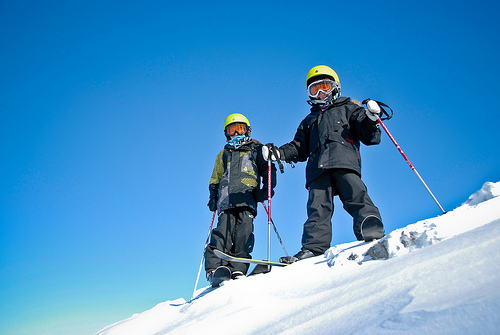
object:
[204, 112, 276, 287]
people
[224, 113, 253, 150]
helmet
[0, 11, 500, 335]
sky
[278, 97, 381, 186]
jacket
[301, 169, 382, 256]
pants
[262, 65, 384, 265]
people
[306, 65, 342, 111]
helmet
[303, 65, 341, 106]
head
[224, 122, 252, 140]
goggles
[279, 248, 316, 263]
boot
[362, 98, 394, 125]
strap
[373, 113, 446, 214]
design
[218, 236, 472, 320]
snow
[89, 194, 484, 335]
ground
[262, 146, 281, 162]
glove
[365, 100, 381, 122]
glove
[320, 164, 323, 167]
button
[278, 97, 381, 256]
snowsuit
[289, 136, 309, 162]
elbow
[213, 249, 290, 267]
ski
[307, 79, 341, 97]
goggles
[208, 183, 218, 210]
gloves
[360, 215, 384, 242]
ski